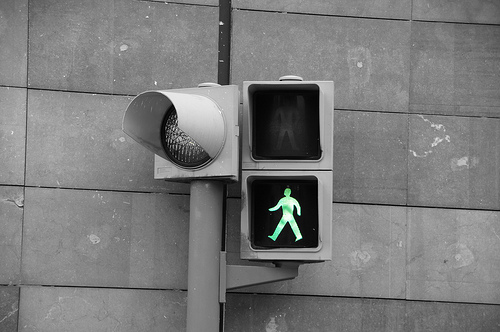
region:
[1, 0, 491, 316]
an old looking wall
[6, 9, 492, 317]
the wall is gray in color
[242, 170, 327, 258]
a crosswalk signal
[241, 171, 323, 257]
a person walking sign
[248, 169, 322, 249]
the person is green in color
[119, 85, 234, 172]
a light on the pole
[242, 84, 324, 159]
a person standing still crosswalk signal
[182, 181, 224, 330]
pole that is gray in color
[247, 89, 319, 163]
The crosswalk signal is not lit up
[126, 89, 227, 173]
The light is off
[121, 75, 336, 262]
Three gray traffic lights.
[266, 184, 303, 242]
A green cartoon man.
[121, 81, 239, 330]
A light on a pole.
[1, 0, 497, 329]
A gray brick wall.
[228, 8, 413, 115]
A block on a wall.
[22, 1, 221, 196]
Two blocks on a wall.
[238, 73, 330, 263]
Two lights on a wall.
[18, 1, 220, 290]
Three blocks on a wall.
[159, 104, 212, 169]
A traffic light lens.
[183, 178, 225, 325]
A gray pole on a wall.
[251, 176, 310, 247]
Green walk light.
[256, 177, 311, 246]
Man on the sign.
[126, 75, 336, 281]
Traffic light on the pole.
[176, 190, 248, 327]
Pole holding traffic lights.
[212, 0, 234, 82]
Black pole on the side of the building.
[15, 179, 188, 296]
Cement block on the building.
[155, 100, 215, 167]
Round light in the pole.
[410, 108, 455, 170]
White stain on the building.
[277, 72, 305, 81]
Knob on top of the light.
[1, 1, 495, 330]
Gray wall in the background.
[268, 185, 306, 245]
A pedestrian symbol that is lighted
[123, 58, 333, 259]
A traffic light by the wall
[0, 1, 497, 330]
A wall behind the traffic light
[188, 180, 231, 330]
The pole connected to the traffic light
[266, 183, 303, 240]
The pedestrian symbol is green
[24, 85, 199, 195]
The wall tile is rectangular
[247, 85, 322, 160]
The stop symbol is not lighted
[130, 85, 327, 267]
A traffic light with a lighted symbol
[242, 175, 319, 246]
The walk symbol is square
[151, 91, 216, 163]
The traffic light is circular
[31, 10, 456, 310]
close-up of a traffic light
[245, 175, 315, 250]
icon for pedestrian crossing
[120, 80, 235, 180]
light for stop and go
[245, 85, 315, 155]
don't cross when lit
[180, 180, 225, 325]
pole on which lights are attached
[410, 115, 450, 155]
water mark on brick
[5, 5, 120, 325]
wall of cinder blocks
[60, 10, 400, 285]
traffic light set against a wall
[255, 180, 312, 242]
green man walking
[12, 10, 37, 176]
line where block fit together